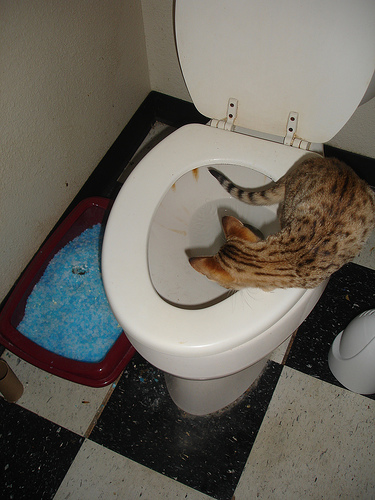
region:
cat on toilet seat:
[95, 2, 373, 417]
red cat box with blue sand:
[1, 195, 124, 390]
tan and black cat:
[186, 157, 373, 295]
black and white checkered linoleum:
[2, 88, 372, 498]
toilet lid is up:
[163, 3, 368, 150]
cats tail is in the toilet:
[202, 160, 302, 208]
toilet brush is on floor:
[328, 306, 373, 405]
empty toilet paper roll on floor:
[1, 356, 27, 410]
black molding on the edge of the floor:
[2, 87, 373, 355]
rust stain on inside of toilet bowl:
[166, 166, 200, 190]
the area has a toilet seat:
[1, 3, 373, 456]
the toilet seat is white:
[74, 5, 374, 490]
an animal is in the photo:
[184, 150, 372, 309]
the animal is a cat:
[163, 150, 374, 312]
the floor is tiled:
[7, 405, 373, 490]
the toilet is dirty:
[147, 155, 250, 215]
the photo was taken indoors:
[5, 4, 374, 499]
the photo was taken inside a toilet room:
[3, 1, 371, 498]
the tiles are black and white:
[10, 396, 372, 497]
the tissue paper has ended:
[0, 346, 31, 418]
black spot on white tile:
[279, 414, 300, 437]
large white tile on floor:
[265, 372, 373, 487]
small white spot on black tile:
[175, 448, 198, 464]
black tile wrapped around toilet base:
[118, 367, 293, 484]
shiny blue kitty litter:
[48, 297, 89, 324]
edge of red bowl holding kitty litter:
[51, 350, 123, 391]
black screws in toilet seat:
[216, 100, 308, 138]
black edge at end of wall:
[132, 90, 181, 115]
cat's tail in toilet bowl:
[192, 164, 318, 200]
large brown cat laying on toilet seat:
[205, 156, 360, 330]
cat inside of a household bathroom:
[9, 10, 369, 443]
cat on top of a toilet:
[108, 6, 372, 434]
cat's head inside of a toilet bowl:
[96, 81, 367, 357]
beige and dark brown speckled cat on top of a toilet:
[96, 74, 373, 364]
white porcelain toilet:
[88, 10, 359, 456]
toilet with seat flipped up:
[84, 0, 373, 375]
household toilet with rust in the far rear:
[92, 89, 347, 403]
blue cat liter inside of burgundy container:
[1, 63, 196, 454]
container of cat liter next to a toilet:
[4, 143, 276, 448]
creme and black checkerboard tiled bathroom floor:
[11, 38, 367, 496]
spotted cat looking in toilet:
[187, 155, 374, 292]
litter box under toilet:
[0, 195, 136, 389]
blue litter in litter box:
[15, 222, 122, 363]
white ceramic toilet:
[99, 0, 374, 416]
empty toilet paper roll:
[0, 358, 25, 401]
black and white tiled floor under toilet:
[0, 120, 374, 499]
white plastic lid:
[329, 309, 374, 395]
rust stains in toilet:
[152, 167, 267, 236]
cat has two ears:
[187, 213, 259, 289]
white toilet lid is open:
[173, 0, 373, 144]